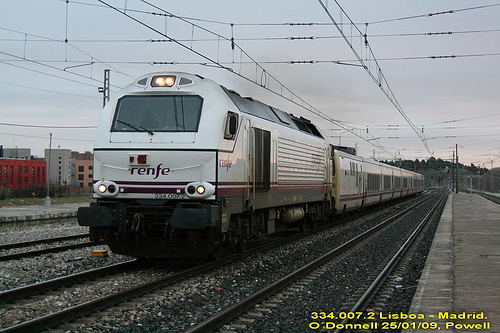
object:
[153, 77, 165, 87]
headlights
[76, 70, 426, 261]
train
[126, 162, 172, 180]
label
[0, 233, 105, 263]
tracks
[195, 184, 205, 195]
headlights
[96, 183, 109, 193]
headlights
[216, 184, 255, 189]
stripes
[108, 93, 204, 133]
windsheild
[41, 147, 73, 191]
building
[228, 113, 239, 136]
mirror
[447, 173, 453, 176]
light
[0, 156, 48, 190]
building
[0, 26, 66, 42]
wires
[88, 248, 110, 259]
object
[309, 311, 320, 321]
watermark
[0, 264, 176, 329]
gravel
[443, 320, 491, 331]
text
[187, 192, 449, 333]
rails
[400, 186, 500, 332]
station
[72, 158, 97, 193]
buildings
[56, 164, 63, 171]
windows